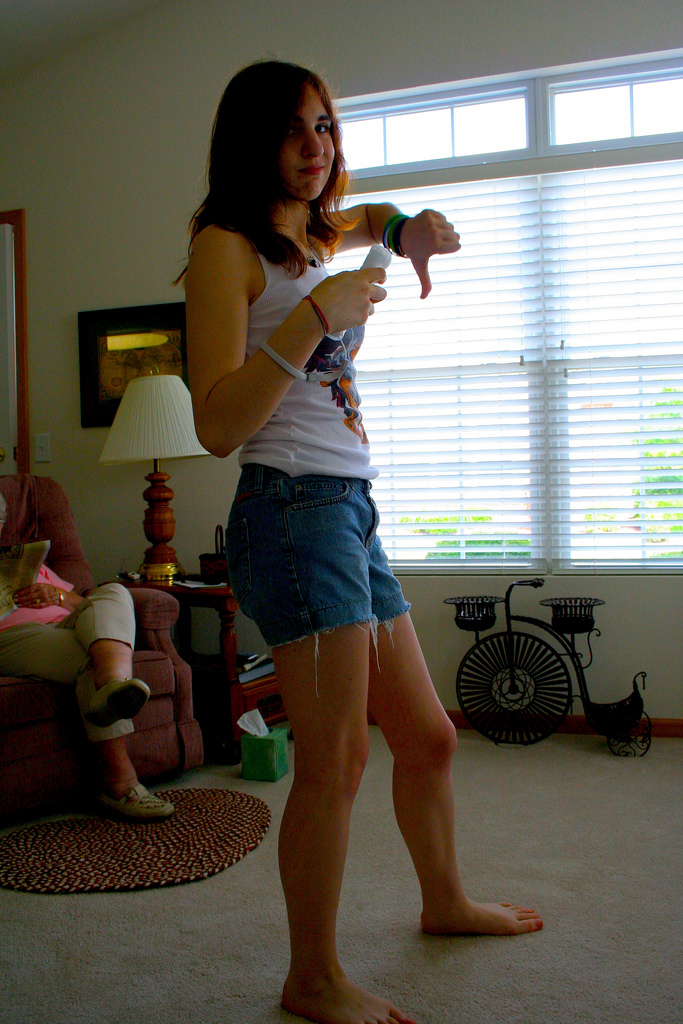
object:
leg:
[256, 561, 377, 1021]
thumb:
[408, 265, 437, 304]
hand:
[307, 265, 391, 326]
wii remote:
[326, 246, 399, 347]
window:
[312, 50, 682, 564]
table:
[134, 566, 255, 764]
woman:
[156, 39, 559, 1016]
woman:
[1, 498, 179, 826]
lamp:
[90, 365, 216, 567]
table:
[125, 570, 246, 739]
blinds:
[339, 41, 681, 585]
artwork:
[68, 298, 199, 437]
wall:
[23, 47, 194, 526]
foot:
[90, 764, 176, 822]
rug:
[0, 778, 274, 898]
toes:
[507, 914, 548, 933]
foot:
[416, 895, 545, 939]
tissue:
[230, 696, 272, 735]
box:
[235, 717, 290, 782]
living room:
[22, 17, 660, 1005]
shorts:
[214, 454, 415, 652]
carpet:
[9, 692, 659, 1006]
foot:
[274, 967, 420, 1022]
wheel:
[453, 633, 572, 753]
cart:
[439, 567, 652, 761]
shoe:
[98, 781, 177, 820]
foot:
[79, 671, 154, 739]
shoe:
[81, 674, 154, 732]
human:
[170, 52, 544, 1022]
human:
[0, 455, 186, 822]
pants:
[0, 578, 138, 743]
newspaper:
[12, 537, 54, 595]